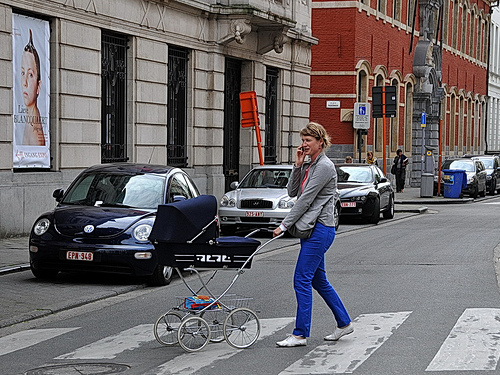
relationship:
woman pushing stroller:
[272, 121, 355, 348] [147, 194, 284, 352]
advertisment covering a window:
[10, 13, 58, 166] [13, 12, 53, 23]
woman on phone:
[272, 121, 355, 348] [297, 148, 304, 164]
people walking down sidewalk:
[347, 149, 417, 199] [395, 189, 422, 213]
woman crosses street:
[281, 111, 363, 345] [44, 235, 484, 373]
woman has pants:
[272, 121, 355, 348] [271, 218, 357, 341]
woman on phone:
[272, 121, 355, 348] [293, 140, 311, 155]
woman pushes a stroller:
[272, 121, 355, 348] [138, 204, 291, 362]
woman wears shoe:
[272, 121, 355, 348] [273, 324, 313, 357]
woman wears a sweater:
[272, 121, 355, 348] [280, 151, 360, 235]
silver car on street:
[220, 156, 348, 261] [223, 189, 428, 316]